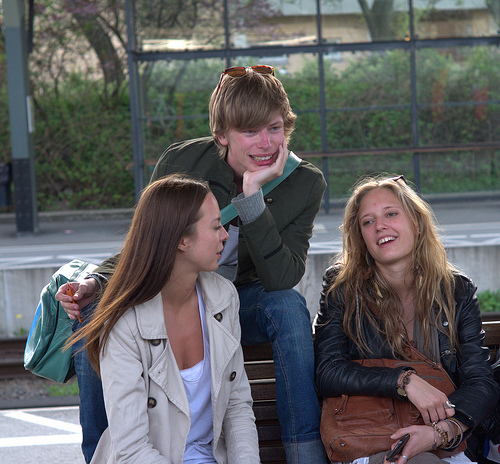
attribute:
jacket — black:
[316, 250, 491, 420]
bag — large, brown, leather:
[319, 355, 455, 458]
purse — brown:
[314, 331, 451, 460]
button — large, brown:
[224, 368, 231, 385]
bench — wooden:
[94, 321, 497, 461]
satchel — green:
[11, 254, 96, 386]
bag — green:
[20, 150, 302, 386]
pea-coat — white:
[94, 273, 261, 462]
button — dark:
[216, 304, 221, 320]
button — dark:
[224, 362, 236, 384]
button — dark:
[142, 370, 150, 380]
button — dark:
[147, 395, 161, 412]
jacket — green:
[88, 141, 328, 286]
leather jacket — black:
[300, 258, 493, 426]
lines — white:
[24, 409, 73, 456]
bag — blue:
[21, 257, 101, 389]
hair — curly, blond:
[315, 172, 463, 359]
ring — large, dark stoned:
[444, 400, 455, 408]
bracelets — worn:
[429, 418, 465, 452]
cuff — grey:
[233, 185, 264, 223]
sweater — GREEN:
[150, 134, 321, 294]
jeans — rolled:
[286, 435, 322, 458]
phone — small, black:
[385, 431, 412, 462]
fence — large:
[125, 0, 497, 211]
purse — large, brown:
[317, 350, 469, 456]